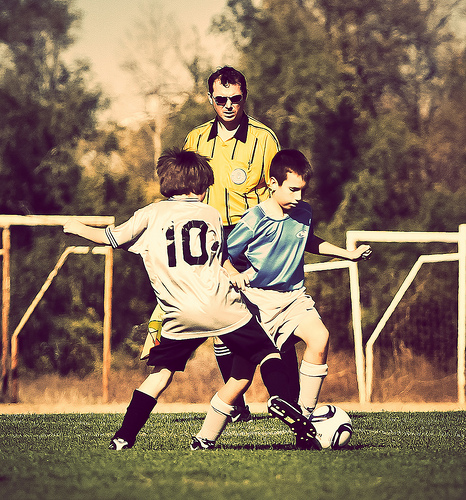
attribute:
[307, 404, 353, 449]
ball — black, white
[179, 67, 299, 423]
man — referee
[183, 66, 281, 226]
shirt — yellow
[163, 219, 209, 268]
number — ten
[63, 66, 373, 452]
people — playing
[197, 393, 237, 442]
socks — white, knee high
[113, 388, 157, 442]
socks — black, knee high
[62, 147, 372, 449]
kids — playing, playing football, young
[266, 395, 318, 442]
shoe — soccer cleat, black, white